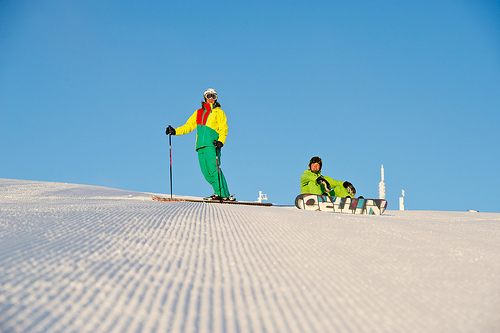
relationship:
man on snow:
[293, 150, 378, 214] [1, 214, 498, 331]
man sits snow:
[293, 150, 378, 214] [1, 214, 498, 331]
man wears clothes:
[293, 150, 378, 214] [171, 100, 417, 245]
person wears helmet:
[182, 70, 228, 109] [184, 85, 229, 114]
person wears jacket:
[182, 70, 228, 109] [286, 166, 371, 204]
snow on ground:
[1, 214, 498, 331] [53, 166, 157, 240]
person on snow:
[182, 70, 228, 109] [1, 214, 498, 331]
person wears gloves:
[182, 70, 228, 109] [150, 119, 235, 165]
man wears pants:
[293, 150, 378, 214] [181, 134, 239, 199]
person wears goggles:
[182, 70, 228, 109] [196, 91, 231, 104]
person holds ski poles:
[182, 70, 228, 109] [151, 123, 246, 208]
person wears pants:
[182, 70, 228, 109] [181, 134, 239, 199]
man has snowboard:
[293, 150, 378, 214] [285, 185, 405, 218]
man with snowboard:
[293, 150, 378, 214] [285, 185, 405, 218]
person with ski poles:
[182, 70, 228, 109] [151, 123, 246, 208]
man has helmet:
[293, 150, 378, 214] [184, 85, 229, 114]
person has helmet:
[182, 70, 228, 109] [184, 85, 229, 114]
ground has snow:
[0, 209, 500, 330] [1, 178, 498, 331]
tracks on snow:
[111, 219, 286, 330] [1, 178, 498, 331]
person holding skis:
[173, 87, 235, 205] [159, 118, 240, 210]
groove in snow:
[193, 197, 207, 331] [1, 178, 498, 331]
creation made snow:
[389, 187, 410, 213] [1, 214, 498, 331]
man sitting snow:
[301, 159, 356, 207] [1, 214, 498, 331]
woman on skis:
[162, 91, 274, 186] [152, 111, 253, 207]